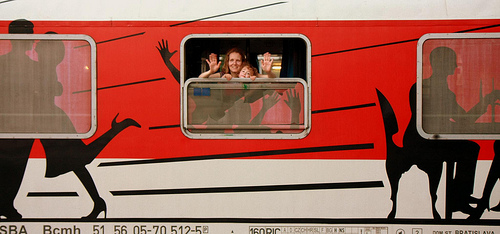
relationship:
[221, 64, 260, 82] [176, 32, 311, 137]
child in window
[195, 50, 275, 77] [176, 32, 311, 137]
adult in window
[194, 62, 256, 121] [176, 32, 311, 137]
child holding onto window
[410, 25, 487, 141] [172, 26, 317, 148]
window with a window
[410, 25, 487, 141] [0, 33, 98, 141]
window with a windows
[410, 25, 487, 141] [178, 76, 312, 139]
window with a covering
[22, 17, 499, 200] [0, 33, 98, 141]
windows that are windows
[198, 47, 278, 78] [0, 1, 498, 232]
adult and child looking out window of a car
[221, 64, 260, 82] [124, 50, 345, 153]
child looking out window of train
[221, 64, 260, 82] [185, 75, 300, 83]
child right hand on window ledge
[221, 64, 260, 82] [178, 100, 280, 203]
child left hand on window ledge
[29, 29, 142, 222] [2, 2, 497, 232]
silhouette of woman dancing on side of train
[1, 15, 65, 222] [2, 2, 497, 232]
silhouette of man dancing on side of train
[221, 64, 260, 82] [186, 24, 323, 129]
child in window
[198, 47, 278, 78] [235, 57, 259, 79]
adult next to kid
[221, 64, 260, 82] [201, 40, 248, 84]
child next to lady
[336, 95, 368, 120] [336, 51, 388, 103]
line on surface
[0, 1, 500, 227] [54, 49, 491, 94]
artwork of photo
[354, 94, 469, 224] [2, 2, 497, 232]
black chair drawn on train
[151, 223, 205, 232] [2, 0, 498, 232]
number on bottom of photo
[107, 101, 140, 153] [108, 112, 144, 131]
painting of heel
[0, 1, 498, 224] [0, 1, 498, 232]
artwork on side of train car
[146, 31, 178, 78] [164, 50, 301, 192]
hand waving out of window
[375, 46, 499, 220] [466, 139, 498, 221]
image of man sitting at table with someone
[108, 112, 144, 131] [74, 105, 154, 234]
heel heels are on feet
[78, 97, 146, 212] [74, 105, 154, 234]
heel heels are on feet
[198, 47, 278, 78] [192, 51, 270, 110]
adult and little girl are smiling